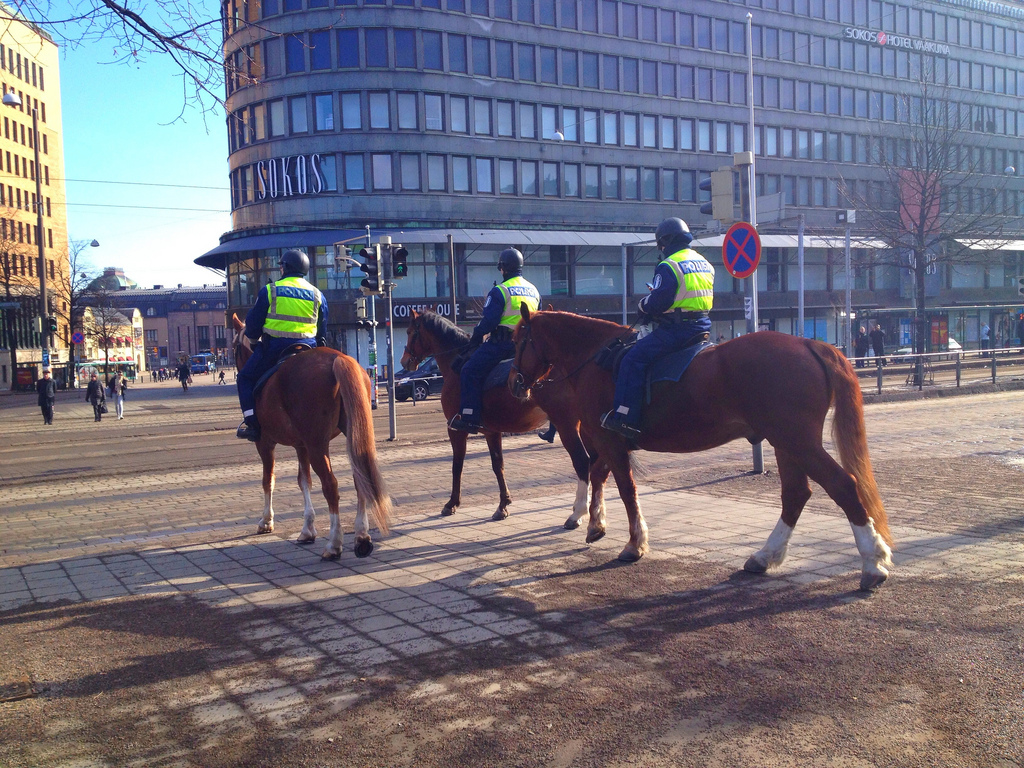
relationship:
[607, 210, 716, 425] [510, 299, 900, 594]
enforcement officer on brown horse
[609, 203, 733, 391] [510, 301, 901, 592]
officer riding brown horse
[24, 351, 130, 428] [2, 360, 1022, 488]
people standing along street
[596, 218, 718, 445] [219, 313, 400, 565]
police officer riding brown horse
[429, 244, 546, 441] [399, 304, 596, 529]
officer riding brown horse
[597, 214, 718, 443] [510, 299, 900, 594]
officer riding brown horse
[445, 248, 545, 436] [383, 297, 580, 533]
officer riding brown horse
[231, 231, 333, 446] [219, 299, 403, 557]
police officer riding brown horse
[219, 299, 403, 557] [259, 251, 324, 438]
brown horse ridden by enforcement officer